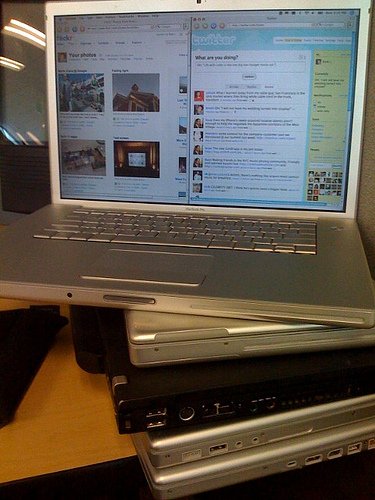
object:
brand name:
[185, 206, 205, 212]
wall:
[0, 144, 62, 219]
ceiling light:
[4, 19, 47, 51]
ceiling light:
[0, 54, 26, 72]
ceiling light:
[27, 130, 44, 145]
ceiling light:
[16, 131, 30, 146]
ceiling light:
[0, 126, 19, 146]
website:
[54, 7, 363, 214]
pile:
[101, 287, 375, 500]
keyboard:
[32, 207, 318, 256]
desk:
[0, 296, 138, 482]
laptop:
[124, 278, 375, 368]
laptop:
[103, 328, 375, 435]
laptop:
[143, 393, 375, 470]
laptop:
[130, 418, 375, 500]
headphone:
[252, 437, 260, 445]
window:
[53, 9, 362, 215]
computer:
[0, 0, 375, 326]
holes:
[252, 436, 259, 444]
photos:
[113, 141, 160, 179]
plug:
[209, 443, 228, 456]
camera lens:
[196, 0, 201, 4]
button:
[331, 226, 344, 232]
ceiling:
[0, 4, 47, 151]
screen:
[55, 9, 362, 212]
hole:
[179, 407, 195, 421]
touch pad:
[80, 248, 214, 287]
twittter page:
[190, 10, 363, 211]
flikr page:
[55, 12, 189, 206]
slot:
[305, 454, 323, 466]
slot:
[327, 447, 343, 459]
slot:
[347, 442, 362, 455]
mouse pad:
[81, 247, 216, 287]